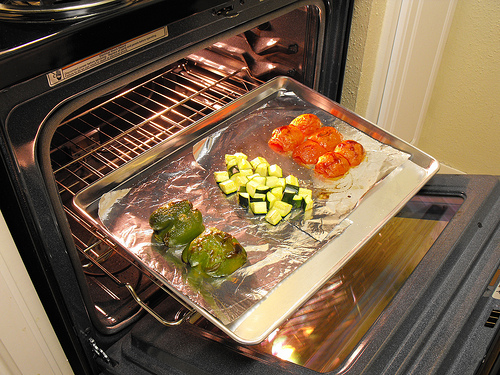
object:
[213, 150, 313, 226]
vegetables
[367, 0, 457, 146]
wall frame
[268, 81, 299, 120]
ground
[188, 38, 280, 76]
light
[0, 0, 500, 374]
oven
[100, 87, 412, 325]
paper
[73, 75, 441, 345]
burner unit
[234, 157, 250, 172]
gogget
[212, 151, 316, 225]
cucumber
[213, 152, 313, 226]
zucchini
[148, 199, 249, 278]
friuts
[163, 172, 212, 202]
aluminum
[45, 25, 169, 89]
label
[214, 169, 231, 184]
slice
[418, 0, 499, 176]
wall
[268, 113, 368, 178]
pan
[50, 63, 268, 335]
rack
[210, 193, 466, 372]
glass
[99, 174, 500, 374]
door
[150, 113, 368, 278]
food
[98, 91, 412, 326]
covering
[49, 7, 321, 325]
window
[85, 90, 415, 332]
soilpaper